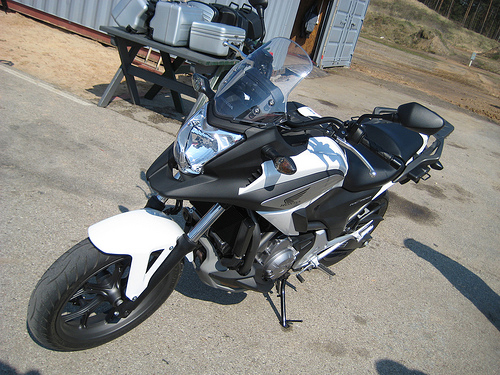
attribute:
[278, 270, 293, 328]
kickstand — black, metal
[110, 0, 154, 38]
container — grey, silver, metal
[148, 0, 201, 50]
container — grey, silver, metal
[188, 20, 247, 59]
container — grey, silver, metal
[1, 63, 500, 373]
road — asphalt, oil slicked, cement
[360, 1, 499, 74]
grass — dry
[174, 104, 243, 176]
headlight — silver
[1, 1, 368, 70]
structure — metal, grey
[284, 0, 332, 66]
door — open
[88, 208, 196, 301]
fender — white, metal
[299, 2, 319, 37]
clothes — grey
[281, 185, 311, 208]
logo — black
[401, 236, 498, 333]
shadow — black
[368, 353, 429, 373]
shadow — black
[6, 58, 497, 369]
pavement — gray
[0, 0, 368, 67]
storage — steel colored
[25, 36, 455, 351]
bike — black, white, parked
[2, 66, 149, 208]
road — cement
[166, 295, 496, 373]
road — cement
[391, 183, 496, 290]
road — cement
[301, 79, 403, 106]
road — cement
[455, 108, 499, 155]
road — cement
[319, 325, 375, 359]
oil spots — brown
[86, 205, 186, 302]
cap — white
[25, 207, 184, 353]
wheel — large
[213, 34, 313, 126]
windshield — high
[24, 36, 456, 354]
motorcycle — gray, black, white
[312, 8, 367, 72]
container — silver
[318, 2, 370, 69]
door — gray, metal, open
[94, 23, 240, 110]
table — grey, wooden, black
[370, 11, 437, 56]
dirt mound — large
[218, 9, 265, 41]
bags — black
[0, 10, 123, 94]
soil — brown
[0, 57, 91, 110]
line — white, Faded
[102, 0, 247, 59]
boxes — metal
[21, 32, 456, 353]
motor bike — black, white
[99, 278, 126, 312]
wheel cap — black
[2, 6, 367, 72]
storage container — metal